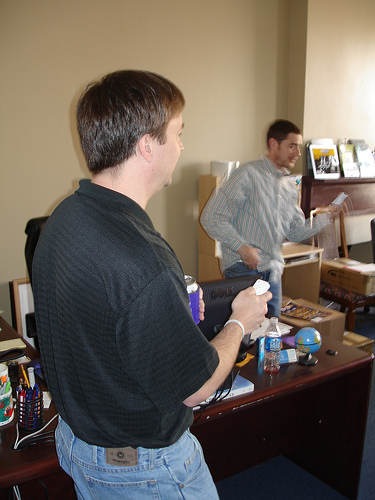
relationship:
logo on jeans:
[102, 445, 139, 472] [49, 416, 223, 494]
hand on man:
[229, 285, 273, 330] [54, 78, 202, 500]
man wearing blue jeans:
[54, 78, 202, 500] [50, 415, 222, 498]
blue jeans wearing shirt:
[50, 415, 222, 498] [40, 203, 203, 450]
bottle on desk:
[260, 313, 284, 376] [0, 316, 373, 499]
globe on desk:
[290, 324, 323, 366] [0, 316, 373, 499]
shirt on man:
[78, 203, 162, 288] [66, 78, 203, 235]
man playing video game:
[66, 78, 203, 235] [239, 274, 274, 329]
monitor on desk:
[197, 270, 269, 354] [0, 316, 373, 499]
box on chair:
[323, 253, 373, 291] [311, 202, 374, 338]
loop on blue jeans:
[149, 450, 154, 471] [61, 432, 217, 497]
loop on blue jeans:
[91, 443, 96, 465] [61, 432, 217, 497]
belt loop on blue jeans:
[68, 431, 76, 457] [61, 432, 217, 497]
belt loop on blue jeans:
[53, 412, 66, 426] [61, 432, 217, 497]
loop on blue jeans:
[186, 424, 191, 434] [61, 432, 217, 497]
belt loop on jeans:
[53, 412, 66, 426] [51, 411, 218, 499]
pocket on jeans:
[170, 432, 212, 496] [53, 419, 230, 492]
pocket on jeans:
[226, 261, 259, 277] [221, 251, 306, 360]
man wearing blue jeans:
[54, 78, 202, 500] [61, 432, 217, 497]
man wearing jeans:
[54, 78, 202, 500] [48, 423, 221, 497]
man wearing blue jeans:
[54, 78, 202, 500] [61, 414, 189, 498]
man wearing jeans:
[54, 78, 202, 500] [91, 446, 185, 490]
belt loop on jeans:
[66, 431, 76, 457] [46, 416, 237, 497]